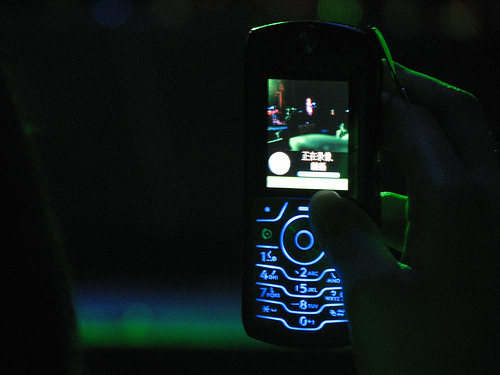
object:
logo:
[300, 150, 333, 162]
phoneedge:
[241, 35, 253, 342]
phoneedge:
[248, 20, 370, 33]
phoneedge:
[361, 37, 380, 216]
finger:
[308, 189, 405, 303]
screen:
[265, 75, 355, 199]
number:
[260, 251, 266, 262]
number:
[260, 270, 269, 280]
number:
[299, 267, 308, 278]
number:
[258, 287, 267, 296]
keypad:
[256, 201, 350, 331]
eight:
[299, 300, 308, 310]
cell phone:
[243, 19, 381, 349]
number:
[299, 283, 307, 294]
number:
[299, 300, 308, 310]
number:
[299, 316, 307, 326]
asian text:
[301, 150, 334, 162]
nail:
[307, 190, 343, 230]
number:
[339, 292, 343, 298]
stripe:
[78, 303, 233, 346]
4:
[259, 269, 269, 280]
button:
[256, 201, 350, 332]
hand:
[307, 59, 500, 375]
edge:
[310, 224, 355, 315]